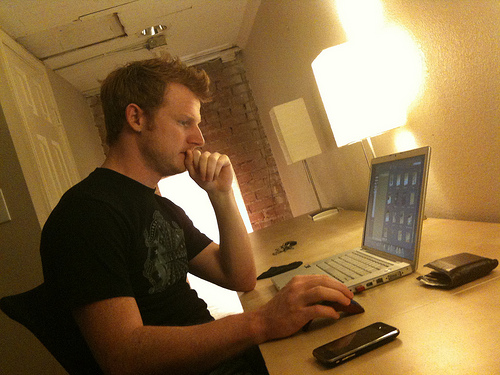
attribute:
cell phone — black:
[302, 317, 402, 370]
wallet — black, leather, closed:
[410, 248, 497, 294]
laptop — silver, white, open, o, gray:
[260, 146, 432, 305]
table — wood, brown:
[216, 202, 497, 374]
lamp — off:
[266, 93, 342, 225]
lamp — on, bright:
[305, 37, 404, 227]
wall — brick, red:
[174, 51, 295, 236]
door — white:
[1, 28, 85, 226]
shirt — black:
[40, 165, 215, 360]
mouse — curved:
[291, 291, 366, 329]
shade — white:
[261, 97, 329, 169]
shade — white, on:
[303, 39, 399, 152]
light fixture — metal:
[137, 24, 171, 52]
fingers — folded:
[190, 150, 231, 187]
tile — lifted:
[6, 12, 144, 63]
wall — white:
[429, 2, 499, 222]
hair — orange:
[102, 59, 211, 137]